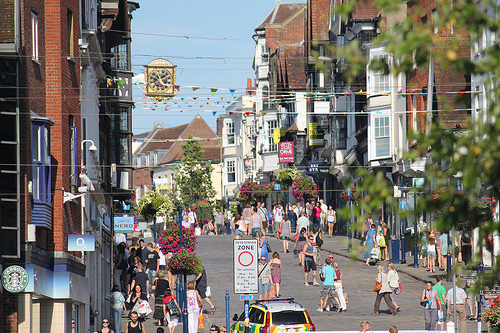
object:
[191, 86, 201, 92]
flags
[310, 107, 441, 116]
line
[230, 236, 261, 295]
sign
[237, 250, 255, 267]
circle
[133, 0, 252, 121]
sky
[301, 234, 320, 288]
man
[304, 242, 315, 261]
tanktop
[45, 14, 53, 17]
bricks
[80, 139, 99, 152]
light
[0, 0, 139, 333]
building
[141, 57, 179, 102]
clock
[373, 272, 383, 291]
purse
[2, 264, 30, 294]
sign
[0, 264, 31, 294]
starbucks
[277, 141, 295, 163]
banner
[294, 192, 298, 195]
flowers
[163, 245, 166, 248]
flowers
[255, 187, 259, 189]
flowers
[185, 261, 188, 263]
flowers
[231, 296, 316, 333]
car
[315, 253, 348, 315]
people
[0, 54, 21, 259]
ladder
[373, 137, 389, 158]
windows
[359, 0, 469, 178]
building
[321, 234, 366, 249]
sidewalk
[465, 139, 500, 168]
branches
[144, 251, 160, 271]
shirt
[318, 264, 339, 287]
shirt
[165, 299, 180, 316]
bag